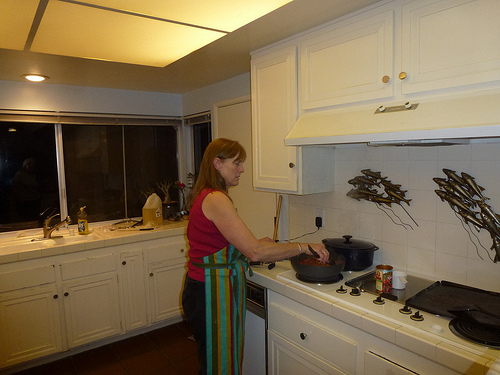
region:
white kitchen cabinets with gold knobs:
[286, 4, 494, 114]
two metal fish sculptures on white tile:
[343, 165, 490, 253]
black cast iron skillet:
[288, 247, 354, 298]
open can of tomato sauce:
[373, 261, 397, 296]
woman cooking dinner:
[173, 123, 341, 372]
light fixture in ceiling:
[6, 62, 78, 98]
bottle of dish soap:
[71, 202, 104, 241]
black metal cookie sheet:
[406, 277, 463, 314]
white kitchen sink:
[8, 209, 114, 262]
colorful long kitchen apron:
[198, 245, 255, 368]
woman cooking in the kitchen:
[162, 131, 397, 367]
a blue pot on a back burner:
[320, 220, 386, 268]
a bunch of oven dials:
[335, 285, 420, 325]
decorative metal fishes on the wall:
[427, 155, 497, 275]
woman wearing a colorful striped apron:
[201, 243, 264, 373]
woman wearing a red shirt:
[177, 185, 233, 281]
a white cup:
[392, 265, 417, 287]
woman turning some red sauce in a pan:
[290, 233, 343, 283]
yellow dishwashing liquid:
[71, 198, 96, 234]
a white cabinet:
[248, 97, 314, 192]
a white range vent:
[279, 94, 499, 143]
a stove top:
[336, 253, 498, 347]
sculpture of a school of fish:
[343, 163, 423, 233]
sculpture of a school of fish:
[423, 165, 497, 267]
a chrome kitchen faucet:
[25, 208, 70, 243]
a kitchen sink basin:
[5, 228, 97, 251]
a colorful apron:
[198, 231, 248, 373]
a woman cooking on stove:
[176, 136, 343, 366]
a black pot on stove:
[314, 229, 380, 276]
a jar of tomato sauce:
[371, 260, 388, 292]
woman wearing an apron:
[205, 171, 274, 373]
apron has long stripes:
[201, 236, 276, 374]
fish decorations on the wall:
[342, 150, 498, 261]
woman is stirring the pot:
[279, 234, 344, 292]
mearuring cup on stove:
[385, 263, 412, 300]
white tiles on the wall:
[425, 228, 469, 276]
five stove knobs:
[335, 281, 445, 342]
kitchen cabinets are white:
[283, 48, 362, 101]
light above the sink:
[9, 59, 69, 112]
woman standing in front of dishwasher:
[222, 260, 285, 366]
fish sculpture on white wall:
[330, 165, 428, 233]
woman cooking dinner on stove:
[170, 133, 284, 373]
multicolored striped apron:
[195, 243, 262, 369]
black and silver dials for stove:
[334, 280, 440, 324]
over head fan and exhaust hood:
[284, 102, 492, 153]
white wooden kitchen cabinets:
[288, 32, 475, 94]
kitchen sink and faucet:
[20, 210, 92, 250]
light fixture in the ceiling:
[16, 62, 60, 96]